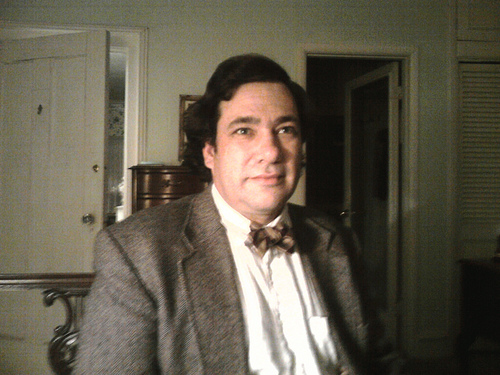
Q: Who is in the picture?
A: Man.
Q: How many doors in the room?
A: 2.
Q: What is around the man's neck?
A: Bow Tie.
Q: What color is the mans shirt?
A: White.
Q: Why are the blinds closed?
A: Privacy.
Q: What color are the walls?
A: White.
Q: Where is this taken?
A: In a house.